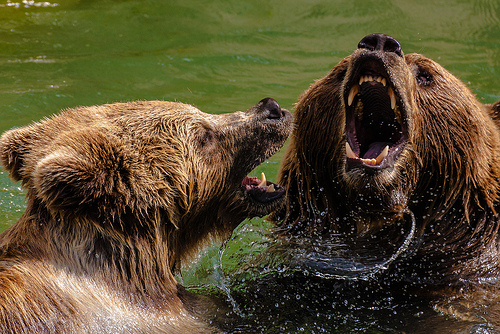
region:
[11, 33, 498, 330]
Two bears in the water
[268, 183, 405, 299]
Water is squishing in the air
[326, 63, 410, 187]
Bear's teeth are yellow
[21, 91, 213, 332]
Bear's fur is brown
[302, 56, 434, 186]
Bear has its mouth open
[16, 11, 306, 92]
The water's color is green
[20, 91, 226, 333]
Bear's fur is wet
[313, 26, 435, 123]
Bear's nose is sticking up in the air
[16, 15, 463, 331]
The bears are grizzly bears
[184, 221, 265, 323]
Water is dripping off the bear's fur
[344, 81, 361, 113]
a sharp tooth in a mouth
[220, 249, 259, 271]
water droplets in the air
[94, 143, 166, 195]
soft brown fur on a bear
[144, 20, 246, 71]
smooth green river water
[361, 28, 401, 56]
big nostrils on a nose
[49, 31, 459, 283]
two bears playing in the water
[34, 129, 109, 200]
a fluffy ear on a head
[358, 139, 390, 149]
a black tongue in a mouth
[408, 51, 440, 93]
an eye in a head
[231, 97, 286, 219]
a large snout on a face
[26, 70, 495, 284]
bears are play fighting in the water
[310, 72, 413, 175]
bears teeth are yellow and sharp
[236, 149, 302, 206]
bears teeth are yellow and sharp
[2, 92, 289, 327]
bear has thick brown fur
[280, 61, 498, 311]
bear has thick brown fur